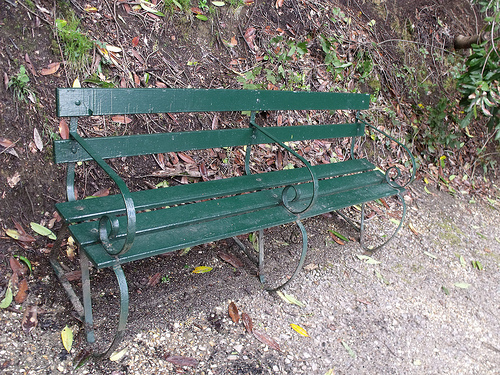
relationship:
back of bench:
[56, 88, 370, 160] [55, 84, 414, 357]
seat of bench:
[50, 158, 405, 266] [55, 84, 414, 357]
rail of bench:
[55, 87, 370, 111] [55, 84, 414, 357]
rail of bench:
[54, 124, 365, 164] [55, 84, 414, 357]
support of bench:
[87, 266, 129, 361] [55, 84, 414, 357]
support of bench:
[267, 220, 310, 292] [55, 84, 414, 357]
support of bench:
[365, 195, 407, 253] [55, 84, 414, 357]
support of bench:
[45, 220, 96, 345] [55, 84, 414, 357]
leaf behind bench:
[31, 220, 57, 240] [55, 84, 414, 357]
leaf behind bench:
[113, 115, 132, 125] [55, 84, 414, 357]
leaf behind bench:
[59, 120, 69, 140] [55, 84, 414, 357]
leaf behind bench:
[179, 151, 195, 165] [55, 84, 414, 357]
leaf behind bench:
[33, 128, 43, 154] [55, 84, 414, 357]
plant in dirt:
[425, 101, 466, 172] [0, 2, 499, 303]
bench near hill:
[55, 84, 414, 357] [0, 0, 499, 307]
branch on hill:
[455, 1, 499, 126] [0, 0, 499, 307]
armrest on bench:
[70, 132, 136, 257] [55, 84, 414, 357]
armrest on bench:
[251, 121, 319, 214] [55, 84, 414, 357]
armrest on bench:
[358, 118, 417, 189] [55, 84, 414, 357]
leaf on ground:
[228, 300, 240, 326] [0, 176, 497, 374]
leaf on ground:
[0, 286, 16, 308] [0, 176, 497, 374]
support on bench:
[45, 220, 96, 345] [55, 84, 414, 357]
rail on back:
[55, 87, 370, 111] [56, 88, 370, 160]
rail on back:
[54, 124, 365, 164] [56, 88, 370, 160]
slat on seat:
[76, 179, 406, 270] [50, 158, 405, 266]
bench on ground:
[55, 84, 414, 357] [0, 176, 497, 374]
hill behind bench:
[0, 0, 499, 307] [55, 84, 414, 357]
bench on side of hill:
[55, 84, 414, 357] [0, 0, 499, 307]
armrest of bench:
[358, 118, 417, 189] [55, 84, 414, 357]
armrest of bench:
[251, 121, 319, 214] [55, 84, 414, 357]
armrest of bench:
[70, 132, 136, 257] [55, 84, 414, 357]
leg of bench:
[79, 252, 132, 360] [55, 84, 414, 357]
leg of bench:
[258, 221, 306, 293] [55, 84, 414, 357]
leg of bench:
[358, 194, 405, 252] [55, 84, 414, 357]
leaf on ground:
[290, 320, 309, 337] [0, 176, 497, 374]